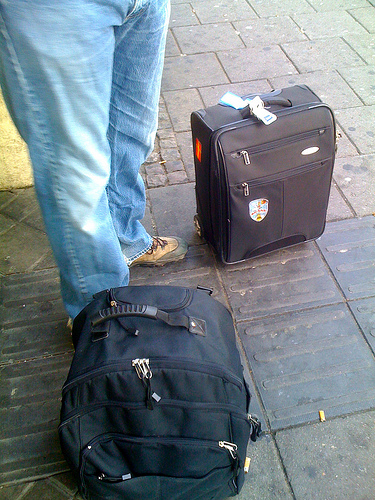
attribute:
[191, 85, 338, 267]
suitcase — black, rolling, rolling type, standing, small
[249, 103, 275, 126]
tag — white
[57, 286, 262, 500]
bag — black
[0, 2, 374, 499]
ground — dark, brick, stone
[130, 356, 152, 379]
zipper — silver, metal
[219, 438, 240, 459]
zipper — silver, metal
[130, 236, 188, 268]
shoe — brown, worn, on foot, black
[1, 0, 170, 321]
jeans — blue, faded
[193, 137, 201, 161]
patch — red, yellow, orange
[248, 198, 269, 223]
patch — white, shield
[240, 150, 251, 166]
zipper — silver, metal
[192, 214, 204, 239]
wheel — black, silver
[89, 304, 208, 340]
handle — black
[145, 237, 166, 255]
lace — brown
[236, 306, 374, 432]
tile — black, metal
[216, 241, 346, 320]
tile — black, metal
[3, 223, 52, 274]
tile — grey